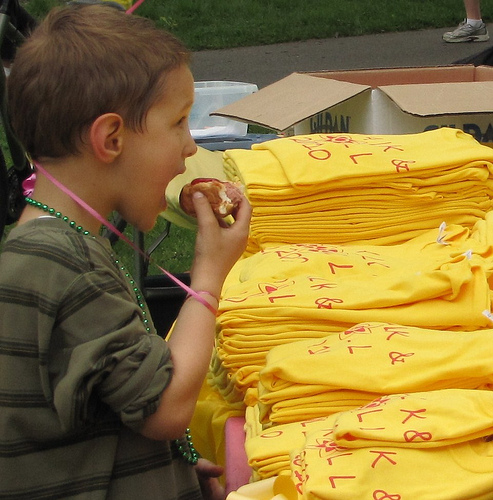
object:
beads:
[50, 204, 57, 215]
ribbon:
[20, 160, 217, 320]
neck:
[9, 153, 116, 237]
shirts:
[248, 126, 492, 188]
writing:
[260, 234, 390, 312]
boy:
[0, 0, 244, 500]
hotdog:
[184, 179, 246, 224]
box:
[207, 65, 492, 140]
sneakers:
[441, 60, 492, 78]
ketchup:
[190, 175, 213, 186]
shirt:
[4, 229, 180, 500]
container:
[185, 78, 260, 141]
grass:
[0, 0, 493, 51]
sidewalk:
[183, 38, 487, 87]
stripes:
[7, 240, 111, 277]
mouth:
[163, 165, 190, 208]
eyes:
[173, 108, 186, 133]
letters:
[304, 141, 331, 163]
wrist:
[174, 274, 225, 305]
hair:
[12, 5, 189, 165]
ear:
[88, 118, 124, 163]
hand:
[187, 186, 250, 292]